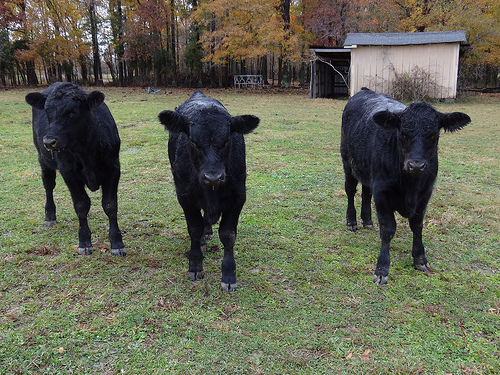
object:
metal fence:
[233, 72, 265, 92]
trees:
[2, 2, 498, 99]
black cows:
[22, 73, 475, 295]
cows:
[19, 75, 466, 290]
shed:
[311, 30, 469, 100]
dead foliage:
[362, 62, 454, 103]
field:
[115, 309, 450, 373]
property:
[3, 84, 498, 373]